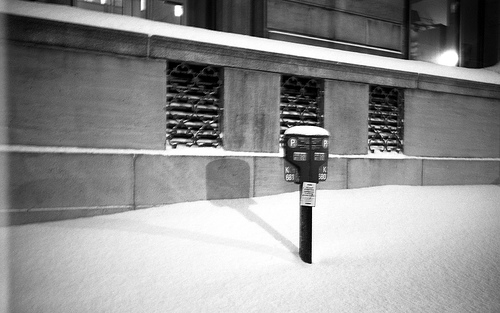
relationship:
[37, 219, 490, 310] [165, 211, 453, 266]
street fill of snow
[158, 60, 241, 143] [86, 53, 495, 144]
window of basement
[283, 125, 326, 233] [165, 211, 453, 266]
parking meter in street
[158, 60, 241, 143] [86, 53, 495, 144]
window of building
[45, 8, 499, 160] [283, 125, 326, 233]
building behind parking meter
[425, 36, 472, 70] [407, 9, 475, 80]
light in window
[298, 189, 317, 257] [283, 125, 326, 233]
pole holds parking meter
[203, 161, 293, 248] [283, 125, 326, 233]
shadow of parking meter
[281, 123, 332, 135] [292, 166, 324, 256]
layer of snow on meter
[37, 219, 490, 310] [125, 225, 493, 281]
large amount of snow on ground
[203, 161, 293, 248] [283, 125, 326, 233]
shadow cast by parking meter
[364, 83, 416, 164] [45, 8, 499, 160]
vents on city building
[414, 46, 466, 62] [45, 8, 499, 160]
reflection on building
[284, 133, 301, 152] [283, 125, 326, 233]
p on parking meter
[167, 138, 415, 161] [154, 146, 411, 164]
snow on on sill under vents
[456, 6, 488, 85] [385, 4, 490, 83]
bars are on windows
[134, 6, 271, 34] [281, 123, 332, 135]
sign in snow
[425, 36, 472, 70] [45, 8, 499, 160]
light on building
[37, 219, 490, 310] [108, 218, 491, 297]
snow on ground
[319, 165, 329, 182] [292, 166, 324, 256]
sign on meter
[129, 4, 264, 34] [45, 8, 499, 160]
decorations on building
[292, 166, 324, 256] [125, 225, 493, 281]
meter covered in snow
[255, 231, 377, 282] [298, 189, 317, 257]
snow covering bottom of pole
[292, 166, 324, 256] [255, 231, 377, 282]
meter covered with snow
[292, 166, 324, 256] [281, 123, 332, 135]
meter on snow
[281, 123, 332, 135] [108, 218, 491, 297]
snow covering ground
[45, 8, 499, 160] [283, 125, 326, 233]
business behind parking meter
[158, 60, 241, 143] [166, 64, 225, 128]
window has bars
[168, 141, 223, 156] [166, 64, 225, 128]
snow on bars